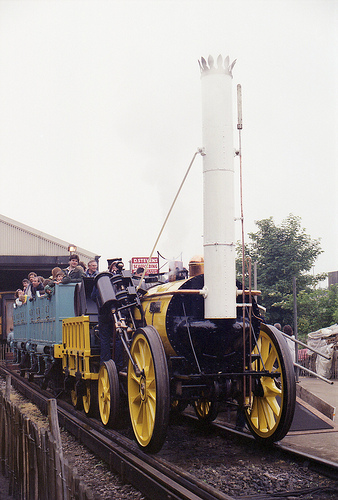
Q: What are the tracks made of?
A: Metal.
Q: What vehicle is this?
A: A steam engine.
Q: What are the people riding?
A: A steam engine.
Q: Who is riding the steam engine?
A: Passengers.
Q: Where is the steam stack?
A: On the steam engine.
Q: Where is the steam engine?
A: On the tracks.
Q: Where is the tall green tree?
A: On the right from the train.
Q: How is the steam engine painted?
A: Yellow and black.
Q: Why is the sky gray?
A: It is cloudy.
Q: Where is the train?
A: On the track.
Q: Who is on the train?
A: A group of people.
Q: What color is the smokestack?
A: White.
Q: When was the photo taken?
A: Daytime.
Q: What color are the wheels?
A: Yellow.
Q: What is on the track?
A: The train.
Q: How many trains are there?
A: One.